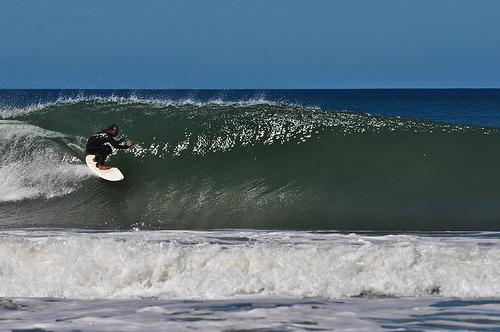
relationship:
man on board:
[72, 120, 125, 162] [85, 154, 124, 181]